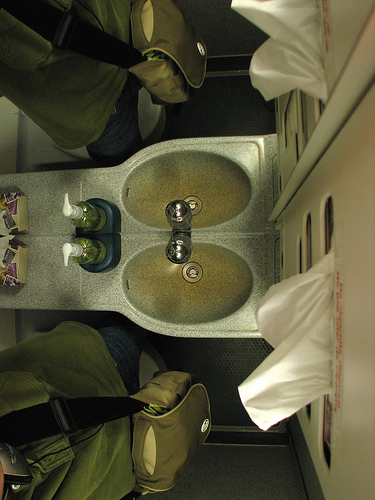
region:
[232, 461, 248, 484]
part of a floor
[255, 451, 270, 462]
part of a floor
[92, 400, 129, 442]
edge of a belt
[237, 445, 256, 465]
part of a floor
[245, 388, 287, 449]
part of a paper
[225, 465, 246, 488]
part of a floor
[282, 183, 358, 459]
a tissue coming from a dispenser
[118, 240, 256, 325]
a grey sink basin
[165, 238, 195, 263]
a chrome water faucet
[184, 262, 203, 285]
a metal sink drain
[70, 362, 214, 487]
a olive colored shoulder bag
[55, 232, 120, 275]
a plastic soap dispenser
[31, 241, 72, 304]
a grey speckled counter top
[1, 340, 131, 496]
a person wearing a green shirt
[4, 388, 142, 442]
a black shoulder strap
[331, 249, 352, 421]
red letter writing on a dispenser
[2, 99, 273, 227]
a mirror in the bathroom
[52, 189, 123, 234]
a soap bottle reflected on mirror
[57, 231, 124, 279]
a bottle of soap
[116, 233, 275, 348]
s sink in the bathroom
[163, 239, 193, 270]
faucet of a sink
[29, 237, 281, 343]
sink is color tan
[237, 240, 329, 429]
a white paper tissue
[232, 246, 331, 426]
tissue in a container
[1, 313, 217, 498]
a person stands in front a sink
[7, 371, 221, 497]
a bag with strap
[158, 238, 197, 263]
The faucet is silver.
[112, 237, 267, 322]
The sink is an oval.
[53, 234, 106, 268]
The soap is next to the sink.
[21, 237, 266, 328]
The counter is tan.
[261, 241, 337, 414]
The tissues are sticking out.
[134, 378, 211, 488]
The pack is tan.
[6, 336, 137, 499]
His jacket is green.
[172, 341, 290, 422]
The floor is gray.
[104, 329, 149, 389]
He is wearing jeans.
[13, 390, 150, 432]
The strap is black.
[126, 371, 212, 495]
Small cloth brown backpack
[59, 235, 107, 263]
Small bottle of hand sanitzer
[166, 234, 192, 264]
Small round metal sink faucet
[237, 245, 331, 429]
Large white billowy towel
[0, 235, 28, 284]
Small square box of paper towels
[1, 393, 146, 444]
Long black cloth strap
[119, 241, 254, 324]
small round bathroom sink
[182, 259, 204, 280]
Metal bathroom sink drain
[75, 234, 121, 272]
Round blue plastic container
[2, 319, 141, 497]
Person with green shirt